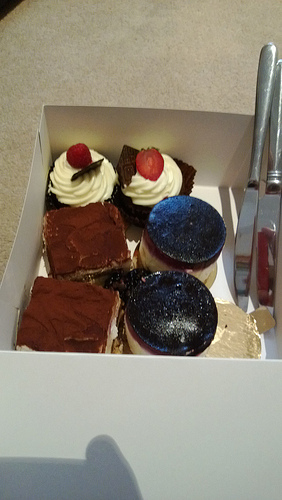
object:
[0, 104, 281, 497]
box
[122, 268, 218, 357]
desserts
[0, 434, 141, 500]
shadow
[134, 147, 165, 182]
strawberry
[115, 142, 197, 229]
cupcake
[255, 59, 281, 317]
butter knife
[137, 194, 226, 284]
dessert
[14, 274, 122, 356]
slice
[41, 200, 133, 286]
cake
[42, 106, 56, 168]
corner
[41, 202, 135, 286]
piece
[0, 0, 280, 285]
tabletop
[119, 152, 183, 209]
whipped cream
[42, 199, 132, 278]
frosting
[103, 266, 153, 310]
berries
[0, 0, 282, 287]
carpet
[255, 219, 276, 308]
reflection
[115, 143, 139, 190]
chocolate wafer